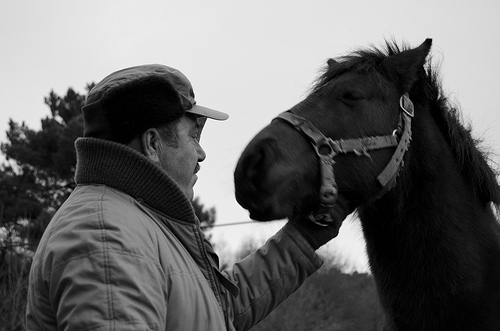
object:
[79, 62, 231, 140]
hat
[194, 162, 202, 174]
mustache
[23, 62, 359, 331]
man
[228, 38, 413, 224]
face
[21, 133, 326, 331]
man/heavy jacket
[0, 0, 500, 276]
sky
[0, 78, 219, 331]
tall tree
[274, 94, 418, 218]
balck strap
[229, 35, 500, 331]
horse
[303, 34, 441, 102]
hair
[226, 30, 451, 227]
horse head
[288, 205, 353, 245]
hand